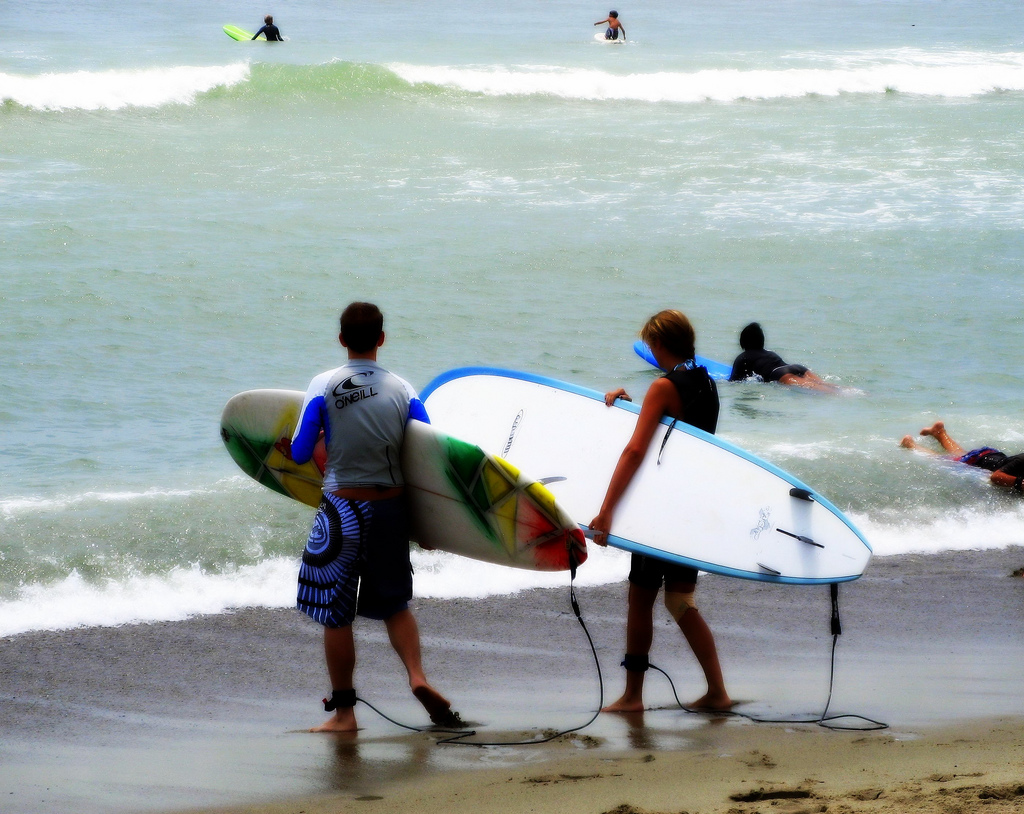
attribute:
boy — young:
[274, 286, 472, 764]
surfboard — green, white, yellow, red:
[205, 374, 598, 586]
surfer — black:
[582, 301, 748, 726]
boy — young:
[591, 5, 629, 50]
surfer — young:
[727, 312, 854, 408]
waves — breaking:
[3, 40, 1021, 124]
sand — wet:
[8, 545, 1021, 809]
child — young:
[890, 409, 1021, 501]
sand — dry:
[355, 722, 1014, 812]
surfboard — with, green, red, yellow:
[217, 387, 582, 564]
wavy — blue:
[8, 2, 1017, 639]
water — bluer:
[5, 2, 1021, 64]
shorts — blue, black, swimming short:
[295, 484, 410, 624]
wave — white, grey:
[7, 419, 1009, 626]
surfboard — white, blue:
[415, 358, 868, 575]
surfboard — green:
[218, 7, 266, 49]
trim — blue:
[434, 348, 519, 379]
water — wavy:
[0, 7, 988, 729]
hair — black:
[616, 290, 707, 362]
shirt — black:
[659, 351, 731, 436]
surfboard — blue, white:
[389, 351, 878, 585]